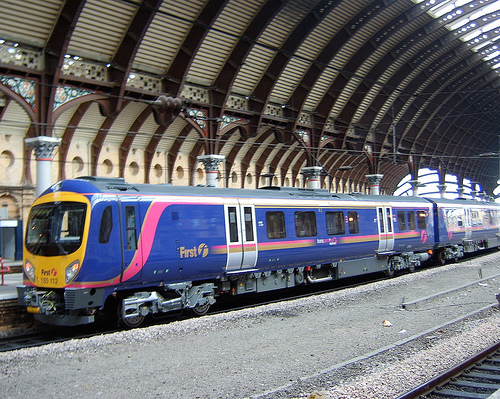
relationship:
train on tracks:
[16, 176, 499, 328] [1, 279, 322, 340]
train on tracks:
[10, 148, 499, 317] [2, 277, 363, 326]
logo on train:
[169, 220, 216, 273] [16, 176, 499, 328]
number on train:
[32, 264, 64, 282] [16, 176, 499, 328]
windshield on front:
[21, 194, 89, 254] [14, 180, 99, 327]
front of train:
[14, 180, 99, 327] [13, 173, 483, 324]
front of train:
[14, 180, 99, 327] [19, 170, 438, 320]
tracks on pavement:
[414, 337, 480, 390] [0, 250, 497, 397]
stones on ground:
[408, 365, 415, 371] [6, 258, 472, 390]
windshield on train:
[24, 200, 88, 258] [19, 170, 438, 320]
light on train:
[61, 258, 81, 282] [19, 170, 438, 320]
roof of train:
[79, 172, 429, 200] [19, 170, 438, 320]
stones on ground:
[346, 324, 485, 394] [6, 258, 472, 390]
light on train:
[71, 262, 78, 271] [19, 170, 438, 320]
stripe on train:
[97, 199, 197, 269] [111, 188, 364, 297]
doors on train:
[240, 204, 257, 267] [255, 180, 479, 280]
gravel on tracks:
[357, 309, 459, 375] [437, 355, 489, 383]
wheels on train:
[189, 284, 212, 315] [80, 193, 384, 286]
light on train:
[71, 262, 78, 271] [64, 176, 359, 274]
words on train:
[171, 232, 226, 260] [86, 192, 376, 301]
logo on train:
[169, 220, 216, 273] [70, 156, 381, 318]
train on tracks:
[16, 176, 499, 328] [212, 289, 289, 311]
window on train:
[21, 209, 90, 254] [44, 158, 357, 302]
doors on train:
[240, 204, 257, 267] [80, 181, 343, 298]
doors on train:
[377, 189, 411, 264] [67, 170, 417, 304]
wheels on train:
[175, 286, 264, 326] [80, 183, 351, 318]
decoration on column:
[29, 136, 67, 156] [19, 136, 59, 188]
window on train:
[247, 190, 303, 251] [142, 194, 376, 291]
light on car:
[71, 262, 78, 271] [29, 175, 322, 308]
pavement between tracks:
[207, 339, 343, 397] [236, 203, 468, 390]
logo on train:
[169, 220, 216, 273] [98, 169, 381, 299]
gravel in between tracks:
[1, 302, 64, 348] [7, 246, 498, 397]